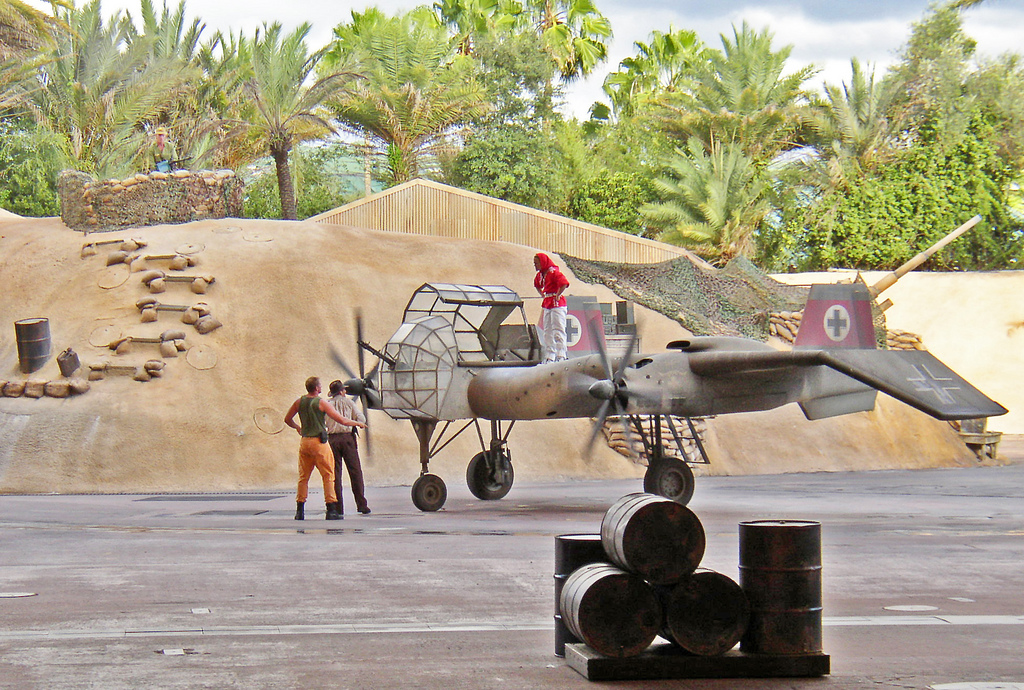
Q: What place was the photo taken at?
A: It was taken at the city.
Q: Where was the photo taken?
A: It was taken at the city.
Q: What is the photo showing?
A: It is showing a city.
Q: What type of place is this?
A: It is a city.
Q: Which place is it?
A: It is a city.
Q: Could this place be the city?
A: Yes, it is the city.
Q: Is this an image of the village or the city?
A: It is showing the city.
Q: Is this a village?
A: No, it is a city.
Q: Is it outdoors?
A: Yes, it is outdoors.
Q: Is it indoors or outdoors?
A: It is outdoors.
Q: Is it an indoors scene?
A: No, it is outdoors.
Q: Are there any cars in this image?
A: No, there are no cars.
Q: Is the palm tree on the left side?
A: Yes, the palm tree is on the left of the image.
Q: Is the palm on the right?
A: No, the palm is on the left of the image.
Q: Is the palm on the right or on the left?
A: The palm is on the left of the image.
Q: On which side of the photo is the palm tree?
A: The palm tree is on the left of the image.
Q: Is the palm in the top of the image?
A: Yes, the palm is in the top of the image.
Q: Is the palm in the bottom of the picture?
A: No, the palm is in the top of the image.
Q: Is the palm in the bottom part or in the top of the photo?
A: The palm is in the top of the image.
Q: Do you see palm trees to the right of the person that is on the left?
A: Yes, there is a palm tree to the right of the person.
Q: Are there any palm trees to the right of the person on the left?
A: Yes, there is a palm tree to the right of the person.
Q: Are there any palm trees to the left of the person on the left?
A: No, the palm tree is to the right of the person.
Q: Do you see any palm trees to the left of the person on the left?
A: No, the palm tree is to the right of the person.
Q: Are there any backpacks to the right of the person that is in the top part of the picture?
A: No, there is a palm tree to the right of the person.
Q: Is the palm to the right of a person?
A: Yes, the palm is to the right of a person.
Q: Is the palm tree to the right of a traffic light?
A: No, the palm tree is to the right of a person.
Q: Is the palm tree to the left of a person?
A: No, the palm tree is to the right of a person.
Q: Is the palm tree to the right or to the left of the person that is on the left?
A: The palm tree is to the right of the person.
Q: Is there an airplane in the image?
A: Yes, there is an airplane.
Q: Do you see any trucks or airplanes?
A: Yes, there is an airplane.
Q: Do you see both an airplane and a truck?
A: No, there is an airplane but no trucks.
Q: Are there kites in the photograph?
A: No, there are no kites.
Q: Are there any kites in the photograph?
A: No, there are no kites.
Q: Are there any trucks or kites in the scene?
A: No, there are no kites or trucks.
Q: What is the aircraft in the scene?
A: The aircraft is an airplane.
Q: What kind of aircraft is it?
A: The aircraft is an airplane.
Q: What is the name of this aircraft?
A: This is an airplane.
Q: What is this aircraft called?
A: This is an airplane.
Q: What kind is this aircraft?
A: This is an airplane.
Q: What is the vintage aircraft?
A: The aircraft is an airplane.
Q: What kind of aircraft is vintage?
A: The aircraft is an airplane.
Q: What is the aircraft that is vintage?
A: The aircraft is an airplane.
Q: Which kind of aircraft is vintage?
A: The aircraft is an airplane.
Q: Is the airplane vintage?
A: Yes, the airplane is vintage.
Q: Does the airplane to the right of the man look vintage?
A: Yes, the plane is vintage.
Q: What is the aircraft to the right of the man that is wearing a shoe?
A: The aircraft is an airplane.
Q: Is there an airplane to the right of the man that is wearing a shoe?
A: Yes, there is an airplane to the right of the man.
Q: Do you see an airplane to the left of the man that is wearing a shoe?
A: No, the airplane is to the right of the man.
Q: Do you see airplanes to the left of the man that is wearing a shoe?
A: No, the airplane is to the right of the man.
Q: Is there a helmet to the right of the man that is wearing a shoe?
A: No, there is an airplane to the right of the man.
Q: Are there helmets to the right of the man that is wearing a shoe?
A: No, there is an airplane to the right of the man.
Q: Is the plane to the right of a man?
A: Yes, the plane is to the right of a man.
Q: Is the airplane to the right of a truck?
A: No, the airplane is to the right of a man.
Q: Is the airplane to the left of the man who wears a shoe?
A: No, the airplane is to the right of the man.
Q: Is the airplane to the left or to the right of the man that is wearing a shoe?
A: The airplane is to the right of the man.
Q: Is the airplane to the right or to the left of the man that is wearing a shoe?
A: The airplane is to the right of the man.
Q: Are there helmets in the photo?
A: No, there are no helmets.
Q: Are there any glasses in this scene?
A: No, there are no glasses.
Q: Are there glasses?
A: No, there are no glasses.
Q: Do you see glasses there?
A: No, there are no glasses.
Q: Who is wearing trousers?
A: The man is wearing trousers.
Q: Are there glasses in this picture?
A: No, there are no glasses.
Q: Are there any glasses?
A: No, there are no glasses.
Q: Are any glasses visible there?
A: No, there are no glasses.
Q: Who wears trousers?
A: The man wears trousers.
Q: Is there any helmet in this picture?
A: No, there are no helmets.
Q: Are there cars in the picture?
A: No, there are no cars.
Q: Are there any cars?
A: No, there are no cars.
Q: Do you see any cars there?
A: No, there are no cars.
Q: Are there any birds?
A: No, there are no birds.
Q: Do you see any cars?
A: No, there are no cars.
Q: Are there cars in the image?
A: No, there are no cars.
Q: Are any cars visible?
A: No, there are no cars.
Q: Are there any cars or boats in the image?
A: No, there are no cars or boats.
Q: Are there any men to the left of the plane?
A: Yes, there is a man to the left of the plane.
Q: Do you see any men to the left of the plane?
A: Yes, there is a man to the left of the plane.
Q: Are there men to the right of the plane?
A: No, the man is to the left of the plane.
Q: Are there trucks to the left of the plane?
A: No, there is a man to the left of the plane.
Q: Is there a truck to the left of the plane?
A: No, there is a man to the left of the plane.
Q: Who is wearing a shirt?
A: The man is wearing a shirt.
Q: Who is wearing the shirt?
A: The man is wearing a shirt.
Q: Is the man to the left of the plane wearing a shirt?
A: Yes, the man is wearing a shirt.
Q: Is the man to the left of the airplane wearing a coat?
A: No, the man is wearing a shirt.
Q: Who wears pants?
A: The man wears pants.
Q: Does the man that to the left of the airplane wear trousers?
A: Yes, the man wears trousers.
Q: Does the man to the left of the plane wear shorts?
A: No, the man wears trousers.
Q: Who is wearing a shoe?
A: The man is wearing a shoe.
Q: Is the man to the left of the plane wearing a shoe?
A: Yes, the man is wearing a shoe.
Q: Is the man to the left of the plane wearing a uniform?
A: No, the man is wearing a shoe.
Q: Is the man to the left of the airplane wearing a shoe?
A: Yes, the man is wearing a shoe.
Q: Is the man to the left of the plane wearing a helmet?
A: No, the man is wearing a shoe.